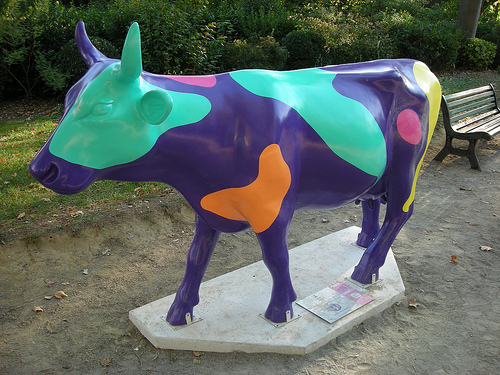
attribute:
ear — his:
[73, 16, 96, 62]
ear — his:
[111, 16, 151, 73]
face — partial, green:
[47, 79, 129, 193]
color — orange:
[189, 139, 305, 236]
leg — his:
[354, 200, 416, 290]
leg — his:
[357, 199, 380, 246]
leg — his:
[247, 211, 299, 323]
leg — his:
[160, 220, 224, 331]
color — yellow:
[409, 62, 439, 224]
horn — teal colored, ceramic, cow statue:
[115, 10, 150, 95]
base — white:
[113, 221, 415, 352]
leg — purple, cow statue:
[166, 225, 231, 327]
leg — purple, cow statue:
[258, 210, 304, 330]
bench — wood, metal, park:
[439, 81, 499, 164]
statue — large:
[30, 14, 446, 344]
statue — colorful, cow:
[22, 19, 450, 323]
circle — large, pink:
[162, 66, 219, 96]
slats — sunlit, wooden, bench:
[443, 88, 495, 123]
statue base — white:
[124, 214, 409, 366]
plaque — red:
[290, 257, 402, 331]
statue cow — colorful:
[17, 15, 462, 327]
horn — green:
[117, 6, 149, 76]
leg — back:
[346, 194, 420, 294]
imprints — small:
[2, 315, 63, 367]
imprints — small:
[75, 230, 142, 280]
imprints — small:
[112, 210, 168, 264]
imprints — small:
[79, 312, 133, 362]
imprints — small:
[159, 355, 191, 367]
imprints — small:
[428, 314, 466, 357]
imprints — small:
[417, 253, 466, 298]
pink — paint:
[397, 116, 418, 136]